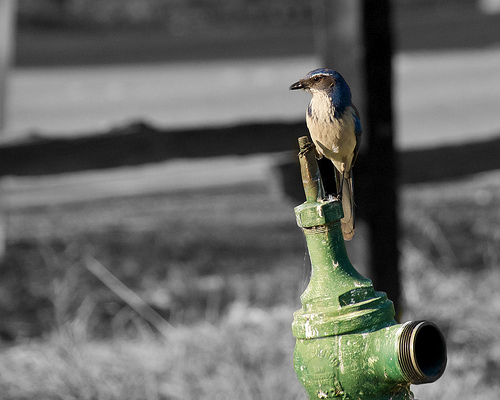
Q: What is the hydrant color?
A: Green.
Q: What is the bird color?
A: Blue.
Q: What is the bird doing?
A: Sitting.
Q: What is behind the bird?
A: Pole.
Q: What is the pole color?
A: Black.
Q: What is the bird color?
A: Blue and white.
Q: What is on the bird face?
A: Beck.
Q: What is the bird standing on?
A: Pipe.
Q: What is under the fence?
A: Grass.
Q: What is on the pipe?
A: A bird.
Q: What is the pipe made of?
A: Metal.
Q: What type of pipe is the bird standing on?
A: Water pipe.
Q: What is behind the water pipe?
A: Fence.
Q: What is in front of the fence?
A: Water pipe.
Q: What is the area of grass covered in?
A: Snow.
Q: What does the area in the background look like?
A: A frozen pond.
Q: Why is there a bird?
A: Resting.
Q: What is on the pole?
A: Bird.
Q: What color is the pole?
A: Green.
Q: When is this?
A: Daytime.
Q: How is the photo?
A: Clear.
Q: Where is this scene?
A: In the field.